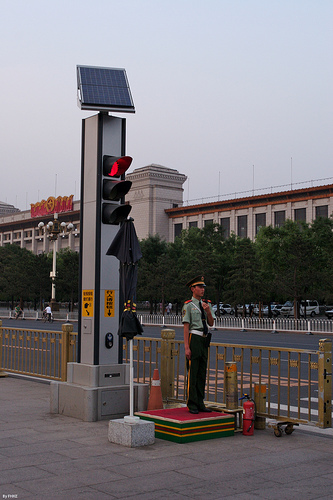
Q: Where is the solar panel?
A: On top of the traffic light.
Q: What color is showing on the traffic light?
A: Red.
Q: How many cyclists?
A: Two.